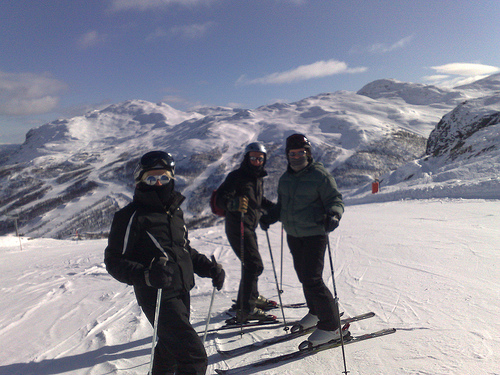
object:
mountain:
[0, 71, 500, 234]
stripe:
[122, 211, 136, 255]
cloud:
[232, 59, 367, 87]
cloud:
[0, 0, 500, 146]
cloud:
[0, 67, 64, 116]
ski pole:
[148, 289, 162, 375]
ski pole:
[203, 286, 217, 345]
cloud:
[58, 31, 104, 47]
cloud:
[77, 0, 218, 51]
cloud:
[423, 63, 500, 90]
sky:
[0, 0, 500, 146]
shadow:
[0, 335, 155, 375]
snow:
[0, 279, 117, 375]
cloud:
[348, 33, 413, 54]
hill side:
[334, 221, 429, 313]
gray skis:
[214, 312, 396, 375]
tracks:
[4, 250, 154, 375]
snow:
[360, 195, 500, 375]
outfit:
[196, 142, 309, 333]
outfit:
[104, 151, 226, 375]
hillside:
[0, 200, 500, 375]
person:
[209, 143, 276, 323]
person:
[259, 133, 344, 346]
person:
[105, 151, 225, 375]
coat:
[104, 182, 212, 306]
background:
[0, 0, 500, 230]